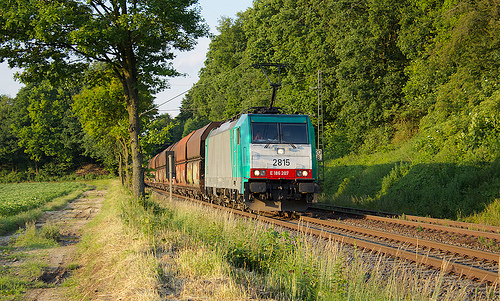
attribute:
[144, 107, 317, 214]
train — long, moving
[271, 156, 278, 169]
number — black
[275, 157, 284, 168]
number — black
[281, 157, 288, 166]
number — black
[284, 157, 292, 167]
number — black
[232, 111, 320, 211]
engine — green, blue, grey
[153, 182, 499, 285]
tracks — metal, brown, railway lines, parallel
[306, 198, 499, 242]
tracks — empty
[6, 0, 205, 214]
tree — leafy, green, growing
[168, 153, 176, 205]
pole — grey, metal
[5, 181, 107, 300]
road — dirt, brown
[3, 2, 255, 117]
sky — blue, clear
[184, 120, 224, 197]
car — rusted, metal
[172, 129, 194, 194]
car — rusted, metal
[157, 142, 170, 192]
car — rusted, metal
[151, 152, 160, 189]
car — rusted, metal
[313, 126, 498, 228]
grass — green